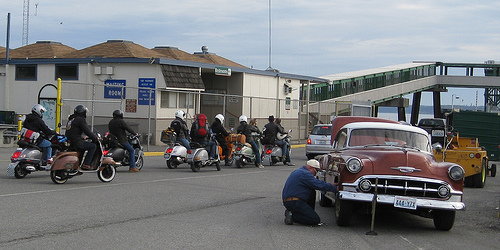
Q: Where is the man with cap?
A: Kneeling next to a car.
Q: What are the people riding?
A: Mopeds.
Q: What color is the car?
A: Brown.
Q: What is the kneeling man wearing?
A: White cap and blue shirt.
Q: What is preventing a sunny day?
A: The clouds.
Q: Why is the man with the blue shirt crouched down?
A: He is changing a tire.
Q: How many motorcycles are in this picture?
A: 8.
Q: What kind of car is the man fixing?
A: Classic.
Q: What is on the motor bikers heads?
A: Helmets.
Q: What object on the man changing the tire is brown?
A: Belt.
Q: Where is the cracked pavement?
A: The street.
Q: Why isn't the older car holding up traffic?
A: It is on the side of the road.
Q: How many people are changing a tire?
A: 1.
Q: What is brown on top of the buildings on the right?
A: Roof.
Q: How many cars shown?
A: 2.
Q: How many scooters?
A: 9.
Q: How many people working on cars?
A: 1.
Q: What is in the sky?
A: Clouds.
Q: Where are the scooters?
A: In road.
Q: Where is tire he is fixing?
A: Right front.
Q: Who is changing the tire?
A: The man.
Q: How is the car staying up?
A: A jack.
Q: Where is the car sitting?
A: Roadside.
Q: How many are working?
A: One.